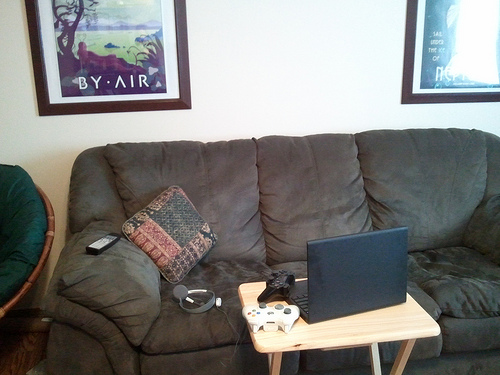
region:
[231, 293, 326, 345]
controller is white with grey sticks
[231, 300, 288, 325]
controller is white with grey sticks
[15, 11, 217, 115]
the photograph with a beautiful scenery on the wall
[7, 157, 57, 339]
the green colored pillow on the wooden chair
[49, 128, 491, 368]
the black colored cushion sofa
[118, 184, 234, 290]
the small mixed colored pillow on the sofa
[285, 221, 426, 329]
the black colored laptop opened on the table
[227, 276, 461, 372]
the brown colored table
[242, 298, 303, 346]
the white colored joystick used to play video games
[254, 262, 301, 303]
the black colored joystick used to play video games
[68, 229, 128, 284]
the black colored remote on the sofa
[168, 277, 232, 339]
the gray colored head phones on the sofa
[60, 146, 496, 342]
The picture has a couch in it.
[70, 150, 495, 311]
The couch is brown.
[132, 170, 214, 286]
In the picture there is a pillow.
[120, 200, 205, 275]
The pillow has multiple colors.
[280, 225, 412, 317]
A laptop is in the picture.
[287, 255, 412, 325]
The laptop is black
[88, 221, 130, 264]
A remote is sitting on the couch.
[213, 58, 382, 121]
The wall is white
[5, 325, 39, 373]
The carpet is brown.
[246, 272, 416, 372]
A table is in the picture.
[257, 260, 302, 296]
controller is black on laptop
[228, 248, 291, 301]
controller is black on laptop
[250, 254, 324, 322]
controller is black on laptop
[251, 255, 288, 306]
controller is black on laptop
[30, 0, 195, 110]
a framed poster hangs on a wall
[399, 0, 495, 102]
a framed poster hangs on a wall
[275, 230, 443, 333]
black laptop computer on a folding table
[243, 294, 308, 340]
video game controller on a folding table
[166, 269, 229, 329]
a headset lies on a couch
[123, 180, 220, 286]
throw pillows on a couch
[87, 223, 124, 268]
television remote control lies on the armrest of a couch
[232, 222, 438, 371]
folding table with electronics on it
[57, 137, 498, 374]
a folding table is set in front of a sofa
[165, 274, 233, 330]
headphones lie on the seat of a sofa